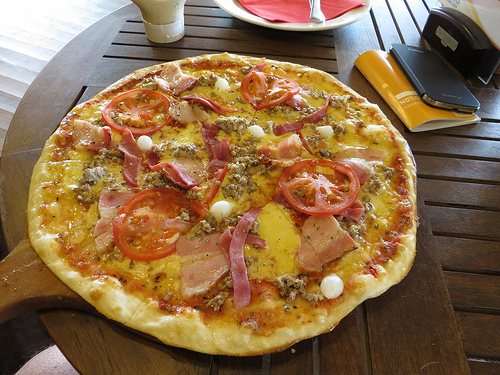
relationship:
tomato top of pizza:
[276, 155, 362, 217] [27, 49, 421, 354]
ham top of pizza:
[228, 201, 261, 309] [27, 49, 421, 354]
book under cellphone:
[353, 48, 480, 131] [390, 39, 481, 114]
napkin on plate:
[238, 1, 366, 23] [212, 0, 372, 32]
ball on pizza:
[315, 275, 346, 300] [27, 49, 421, 354]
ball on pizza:
[135, 134, 155, 150] [27, 49, 421, 354]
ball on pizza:
[210, 199, 233, 220] [27, 49, 421, 354]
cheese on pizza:
[249, 200, 299, 277] [27, 49, 421, 354]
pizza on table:
[27, 49, 421, 354] [0, 2, 497, 372]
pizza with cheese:
[27, 49, 421, 354] [110, 257, 178, 296]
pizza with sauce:
[27, 49, 421, 354] [374, 153, 413, 262]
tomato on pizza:
[112, 184, 209, 258] [27, 49, 421, 354]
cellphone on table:
[390, 39, 481, 114] [0, 2, 497, 372]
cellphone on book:
[390, 39, 481, 114] [353, 48, 480, 131]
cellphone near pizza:
[390, 39, 481, 114] [27, 49, 421, 354]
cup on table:
[128, 1, 187, 43] [0, 2, 497, 372]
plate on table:
[212, 0, 372, 32] [0, 2, 497, 372]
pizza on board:
[27, 49, 421, 354] [1, 237, 96, 320]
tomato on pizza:
[99, 85, 177, 134] [27, 49, 421, 354]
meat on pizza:
[295, 213, 359, 273] [27, 49, 421, 354]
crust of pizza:
[86, 275, 284, 354] [27, 49, 421, 354]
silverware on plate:
[307, 1, 327, 25] [212, 0, 372, 32]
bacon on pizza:
[272, 92, 336, 133] [27, 49, 421, 354]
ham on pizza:
[228, 201, 261, 309] [27, 49, 421, 354]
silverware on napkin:
[307, 1, 327, 25] [238, 1, 366, 23]